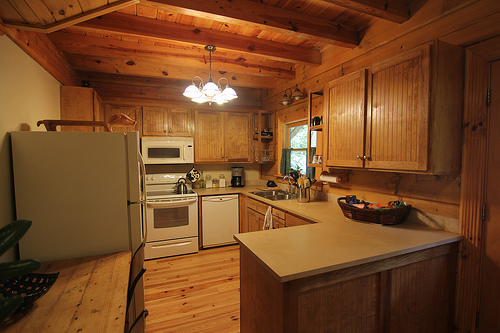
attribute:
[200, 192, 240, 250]
dishwasher — white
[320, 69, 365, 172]
overhead cabinet — wooden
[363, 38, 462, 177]
overhead cabinet — wooden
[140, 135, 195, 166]
microwave oven — hanging overhead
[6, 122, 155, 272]
refrigerator — white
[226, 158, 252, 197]
processor — black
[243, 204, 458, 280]
counter — kitchen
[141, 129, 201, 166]
microwave — one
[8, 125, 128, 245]
side — one, fridge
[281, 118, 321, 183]
window — one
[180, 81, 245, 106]
light — one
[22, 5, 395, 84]
ceiling — one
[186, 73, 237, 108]
lights — white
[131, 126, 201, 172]
microwave — white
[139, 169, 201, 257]
range — white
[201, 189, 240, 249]
door — white, dishwasher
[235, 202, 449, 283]
counter — white, kitchen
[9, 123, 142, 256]
fridge — white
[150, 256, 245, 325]
floor — brown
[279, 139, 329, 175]
curtain — green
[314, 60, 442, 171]
cabinets — brown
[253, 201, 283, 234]
towel — one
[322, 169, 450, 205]
panels — wooden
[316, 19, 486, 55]
panels — wooden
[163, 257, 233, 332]
panels — wooden 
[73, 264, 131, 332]
panels — wooden 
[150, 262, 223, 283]
panels — wooden 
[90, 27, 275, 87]
panels — wooden 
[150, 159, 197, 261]
stove — white 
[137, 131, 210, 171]
microwave — white 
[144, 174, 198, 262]
stove — white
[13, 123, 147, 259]
refrigerator — white 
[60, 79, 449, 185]
cabinets — wooden 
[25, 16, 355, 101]
beams — wooden 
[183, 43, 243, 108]
light — hanging 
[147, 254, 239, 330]
floors — hardwood, pale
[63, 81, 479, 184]
cabinets — pale, hardwood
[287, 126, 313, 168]
greenery — some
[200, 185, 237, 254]
dishwasher — one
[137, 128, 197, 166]
microwave — one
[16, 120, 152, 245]
sideview — fridge